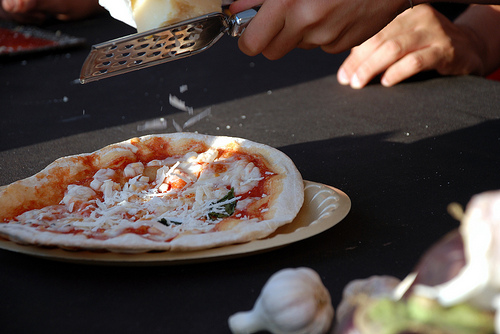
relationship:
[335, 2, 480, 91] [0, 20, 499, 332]
hand on table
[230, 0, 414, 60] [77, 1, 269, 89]
hand holding grater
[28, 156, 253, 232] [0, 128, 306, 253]
cheese sprinkled on pizza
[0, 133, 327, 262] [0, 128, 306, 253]
grated cheese on pizza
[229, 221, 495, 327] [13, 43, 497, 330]
veggies on table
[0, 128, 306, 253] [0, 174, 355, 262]
pizza on plate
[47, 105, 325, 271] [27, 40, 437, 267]
plate on table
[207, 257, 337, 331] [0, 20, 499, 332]
garlic on table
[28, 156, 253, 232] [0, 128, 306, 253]
cheese on pizza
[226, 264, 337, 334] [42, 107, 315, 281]
garlic in corner of pizza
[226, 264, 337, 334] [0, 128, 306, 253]
garlic in corner of pizza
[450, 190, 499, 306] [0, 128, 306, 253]
garlic in corner of pizza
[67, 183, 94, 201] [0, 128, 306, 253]
garlic in corner of pizza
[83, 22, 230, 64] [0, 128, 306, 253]
garlic in corner of pizza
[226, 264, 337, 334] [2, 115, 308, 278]
garlic in corner of pizza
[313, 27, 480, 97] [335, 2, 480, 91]
fingers on hand